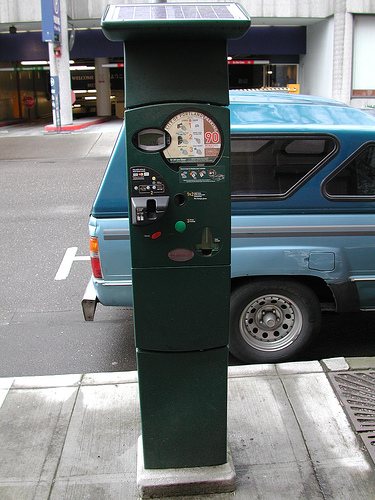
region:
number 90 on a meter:
[203, 130, 219, 144]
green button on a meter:
[174, 219, 187, 232]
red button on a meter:
[149, 228, 163, 240]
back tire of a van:
[217, 270, 326, 364]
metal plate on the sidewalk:
[327, 366, 374, 481]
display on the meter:
[137, 132, 163, 151]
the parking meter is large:
[100, 1, 252, 470]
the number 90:
[205, 131, 221, 143]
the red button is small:
[150, 229, 160, 239]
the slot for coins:
[199, 227, 216, 256]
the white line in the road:
[53, 246, 89, 277]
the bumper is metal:
[80, 275, 97, 322]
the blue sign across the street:
[39, 1, 61, 44]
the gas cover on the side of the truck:
[308, 251, 335, 273]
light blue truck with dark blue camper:
[74, 93, 374, 339]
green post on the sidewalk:
[100, 3, 256, 494]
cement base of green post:
[128, 429, 232, 498]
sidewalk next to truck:
[4, 363, 369, 498]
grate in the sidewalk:
[328, 368, 374, 464]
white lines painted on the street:
[38, 238, 89, 284]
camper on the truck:
[94, 96, 373, 219]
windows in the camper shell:
[228, 137, 373, 195]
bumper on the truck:
[79, 283, 96, 316]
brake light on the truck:
[91, 257, 99, 279]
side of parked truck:
[88, 97, 373, 364]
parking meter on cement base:
[102, 7, 250, 497]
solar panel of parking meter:
[103, 1, 249, 36]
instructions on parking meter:
[163, 109, 220, 169]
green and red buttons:
[151, 220, 185, 239]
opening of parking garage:
[2, 16, 330, 132]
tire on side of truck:
[227, 278, 313, 363]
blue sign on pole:
[41, 0, 64, 127]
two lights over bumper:
[81, 235, 103, 322]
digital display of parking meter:
[133, 125, 171, 152]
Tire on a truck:
[217, 272, 334, 365]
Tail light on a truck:
[84, 232, 109, 282]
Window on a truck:
[216, 123, 352, 207]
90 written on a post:
[201, 130, 221, 148]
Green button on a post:
[171, 211, 188, 235]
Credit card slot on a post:
[132, 194, 172, 229]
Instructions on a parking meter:
[143, 108, 225, 174]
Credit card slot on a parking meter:
[133, 195, 170, 224]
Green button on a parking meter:
[168, 217, 197, 237]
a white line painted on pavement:
[54, 240, 85, 285]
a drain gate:
[325, 362, 373, 450]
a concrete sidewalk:
[15, 365, 128, 498]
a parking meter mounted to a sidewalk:
[125, 10, 243, 498]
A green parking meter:
[63, 44, 252, 290]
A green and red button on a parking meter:
[133, 205, 203, 263]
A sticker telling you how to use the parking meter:
[167, 108, 217, 196]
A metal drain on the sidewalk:
[297, 369, 368, 453]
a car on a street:
[77, 85, 373, 361]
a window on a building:
[0, 71, 19, 122]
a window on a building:
[31, 68, 52, 121]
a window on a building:
[110, 65, 121, 91]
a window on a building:
[265, 64, 298, 88]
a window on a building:
[227, 62, 265, 91]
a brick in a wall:
[320, 19, 328, 22]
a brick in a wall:
[327, 32, 334, 40]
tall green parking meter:
[123, 5, 231, 480]